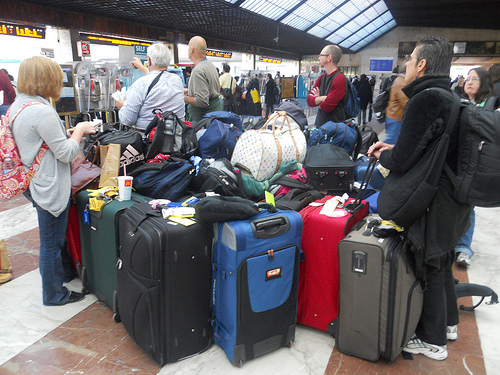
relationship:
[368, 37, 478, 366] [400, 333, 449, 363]
man wears shoe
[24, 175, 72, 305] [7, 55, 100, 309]
leg belongs to woman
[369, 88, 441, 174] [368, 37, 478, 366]
arm belongs to man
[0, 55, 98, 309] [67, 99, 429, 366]
woman with luggage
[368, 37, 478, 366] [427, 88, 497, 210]
man has backpack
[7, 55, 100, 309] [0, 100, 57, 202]
woman wears backpack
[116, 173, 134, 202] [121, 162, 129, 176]
cup has straw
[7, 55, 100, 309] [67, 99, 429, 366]
woman next to luggage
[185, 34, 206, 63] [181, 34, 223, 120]
head belongs to man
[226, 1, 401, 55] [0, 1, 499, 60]
window along roof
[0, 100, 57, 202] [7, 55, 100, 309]
backpack belongs to woman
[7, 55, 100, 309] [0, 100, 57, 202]
woman has backpack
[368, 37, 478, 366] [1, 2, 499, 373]
man in airport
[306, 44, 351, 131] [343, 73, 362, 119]
man has backpack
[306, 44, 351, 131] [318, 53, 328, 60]
man has eyeglasses